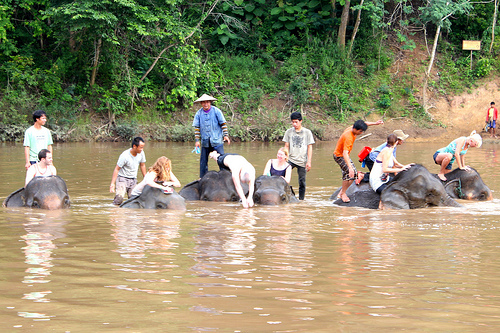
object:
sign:
[460, 38, 482, 70]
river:
[0, 135, 500, 328]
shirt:
[279, 124, 314, 173]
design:
[288, 131, 306, 149]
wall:
[407, 104, 454, 140]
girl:
[129, 155, 181, 199]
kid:
[484, 100, 498, 139]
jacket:
[484, 106, 500, 123]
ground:
[400, 127, 434, 169]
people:
[353, 129, 410, 186]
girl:
[432, 129, 484, 182]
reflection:
[11, 203, 69, 309]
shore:
[7, 102, 499, 143]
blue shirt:
[192, 104, 230, 147]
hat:
[192, 91, 219, 105]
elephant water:
[255, 172, 300, 225]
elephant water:
[329, 163, 463, 218]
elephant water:
[116, 184, 186, 226]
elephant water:
[0, 173, 71, 227]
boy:
[330, 117, 385, 203]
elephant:
[252, 174, 301, 206]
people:
[191, 92, 230, 183]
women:
[261, 145, 293, 183]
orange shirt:
[331, 124, 355, 157]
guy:
[332, 118, 384, 203]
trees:
[0, 0, 409, 120]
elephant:
[176, 170, 249, 202]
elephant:
[429, 165, 493, 201]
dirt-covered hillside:
[371, 32, 498, 148]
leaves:
[70, 8, 119, 40]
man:
[206, 148, 261, 209]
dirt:
[395, 47, 420, 70]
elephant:
[327, 160, 460, 210]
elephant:
[115, 183, 187, 210]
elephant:
[0, 175, 72, 212]